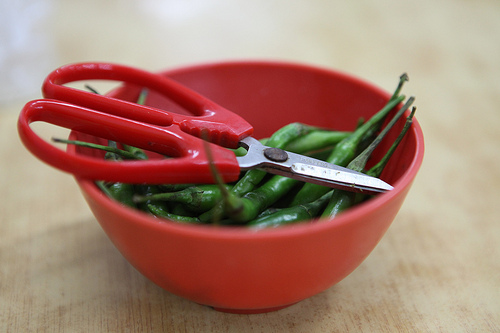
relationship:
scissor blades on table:
[240, 130, 404, 196] [389, 240, 496, 332]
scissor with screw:
[119, 97, 360, 220] [262, 138, 276, 171]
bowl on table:
[62, 54, 427, 314] [0, 2, 496, 332]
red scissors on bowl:
[23, 56, 396, 196] [62, 54, 427, 314]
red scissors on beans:
[23, 56, 396, 196] [52, 73, 415, 228]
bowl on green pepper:
[62, 54, 427, 314] [104, 65, 414, 222]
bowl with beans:
[63, 57, 425, 314] [52, 73, 415, 228]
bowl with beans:
[62, 54, 427, 314] [256, 70, 418, 175]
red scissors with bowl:
[23, 56, 396, 196] [62, 54, 427, 314]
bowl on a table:
[62, 54, 427, 314] [0, 2, 496, 332]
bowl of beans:
[62, 54, 427, 314] [93, 103, 400, 221]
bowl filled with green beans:
[62, 54, 427, 314] [51, 72, 416, 229]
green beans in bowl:
[51, 72, 416, 229] [62, 54, 427, 314]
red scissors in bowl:
[23, 56, 396, 196] [38, 45, 440, 330]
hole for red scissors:
[33, 117, 178, 162] [23, 56, 396, 196]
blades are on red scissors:
[237, 146, 392, 191] [23, 56, 396, 196]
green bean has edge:
[331, 72, 411, 162] [361, 77, 406, 171]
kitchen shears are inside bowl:
[17, 59, 397, 194] [62, 54, 427, 314]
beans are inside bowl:
[52, 73, 415, 228] [62, 54, 427, 314]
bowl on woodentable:
[63, 57, 425, 314] [434, 52, 472, 139]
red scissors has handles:
[23, 56, 396, 196] [33, 99, 190, 166]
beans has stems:
[253, 82, 404, 228] [109, 92, 413, 223]